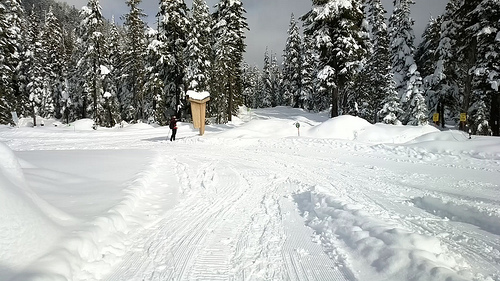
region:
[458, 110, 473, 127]
yellow informational sign on snow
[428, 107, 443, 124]
yellow informational sign on snow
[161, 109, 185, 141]
person standing in the snow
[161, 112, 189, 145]
person wearing dark clothes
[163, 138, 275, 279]
tracks in snowy path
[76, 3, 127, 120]
tall snow covered tree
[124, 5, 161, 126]
tall snow covered tree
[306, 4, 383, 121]
tall snow covered tree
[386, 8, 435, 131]
tall snow covered tree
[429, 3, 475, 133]
tall snow covered tree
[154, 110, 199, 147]
a lone cross country skiier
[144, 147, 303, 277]
there appears to have been much traffic here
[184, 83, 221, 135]
a wooden box type thing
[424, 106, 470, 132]
yellow signs on the trees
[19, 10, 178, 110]
the evergreens are laden with snow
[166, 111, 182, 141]
the person is dressed in black mostly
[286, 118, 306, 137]
some type of sign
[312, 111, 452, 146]
the snow is piled up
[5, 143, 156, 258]
the snow here appears to be drifted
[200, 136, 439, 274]
it appears this is quite heavily traversed area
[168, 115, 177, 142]
A skier on the snow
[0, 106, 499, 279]
Ground covered with snow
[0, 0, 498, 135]
Big green trees covered with snow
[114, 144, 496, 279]
Ski trails on the snow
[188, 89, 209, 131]
A pillar on the edge of the snow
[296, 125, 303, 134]
A small marker pole on the snow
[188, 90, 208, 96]
Snow on top of the pillar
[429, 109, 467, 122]
Two small signs under the trees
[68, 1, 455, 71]
A mountain in the background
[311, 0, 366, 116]
One of the many trees with snow on them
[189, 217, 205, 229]
pile of white snow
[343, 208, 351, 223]
pile of white snow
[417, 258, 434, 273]
pile of white snow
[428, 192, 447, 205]
pile of white snow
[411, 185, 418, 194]
pile of white snow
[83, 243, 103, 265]
pile of white snow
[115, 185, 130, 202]
pile of white snow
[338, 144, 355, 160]
pile of white snow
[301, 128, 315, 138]
pile of white snow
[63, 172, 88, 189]
pile of white snow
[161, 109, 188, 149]
person using snowboard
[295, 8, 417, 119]
pine tree covered by snow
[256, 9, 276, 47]
sky with clouds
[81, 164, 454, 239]
place full of snow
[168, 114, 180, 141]
a person wearing snowsuit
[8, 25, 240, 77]
lot of pine trees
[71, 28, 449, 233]
trees in the snow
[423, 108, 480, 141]
yellow color board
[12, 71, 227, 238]
snow, person and pine trees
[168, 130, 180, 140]
leg of the snow